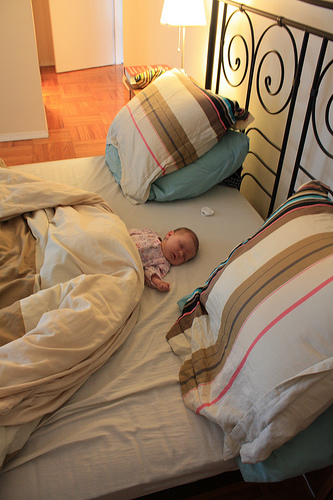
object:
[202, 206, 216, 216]
teether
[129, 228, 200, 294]
baby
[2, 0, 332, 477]
bed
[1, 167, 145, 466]
comforter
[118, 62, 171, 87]
book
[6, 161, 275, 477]
sheet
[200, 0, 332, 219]
bed frame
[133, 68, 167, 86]
bag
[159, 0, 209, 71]
lamp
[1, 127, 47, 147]
baseboard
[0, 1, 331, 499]
bedroom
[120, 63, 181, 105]
table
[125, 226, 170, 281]
onesie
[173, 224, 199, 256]
hair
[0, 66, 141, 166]
floor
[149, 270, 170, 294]
arm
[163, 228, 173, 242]
ear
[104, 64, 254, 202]
pillow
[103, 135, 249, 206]
pillow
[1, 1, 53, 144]
wall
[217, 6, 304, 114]
curls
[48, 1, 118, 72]
door